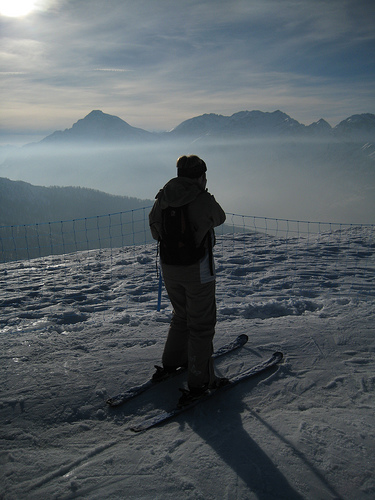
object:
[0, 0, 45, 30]
sun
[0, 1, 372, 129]
sky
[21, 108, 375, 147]
mountain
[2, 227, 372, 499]
snow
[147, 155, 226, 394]
person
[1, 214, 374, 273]
fence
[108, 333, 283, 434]
ski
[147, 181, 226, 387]
snow suit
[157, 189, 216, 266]
backpack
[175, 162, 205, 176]
head band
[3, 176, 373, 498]
hill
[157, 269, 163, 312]
ski pole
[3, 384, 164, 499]
tracks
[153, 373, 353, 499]
shadow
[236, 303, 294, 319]
pit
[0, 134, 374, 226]
mist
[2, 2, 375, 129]
cloud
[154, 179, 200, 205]
hood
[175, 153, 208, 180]
hat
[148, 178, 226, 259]
coat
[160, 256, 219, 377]
pants